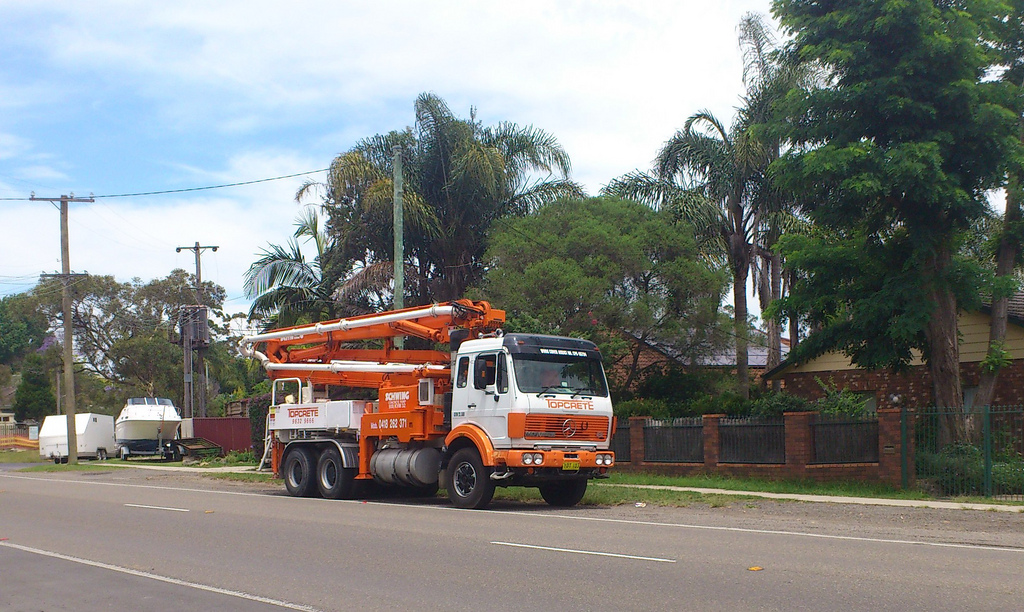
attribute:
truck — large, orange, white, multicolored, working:
[238, 290, 621, 521]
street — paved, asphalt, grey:
[2, 448, 1023, 612]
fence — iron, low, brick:
[586, 405, 929, 490]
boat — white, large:
[106, 394, 189, 455]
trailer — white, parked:
[36, 412, 121, 464]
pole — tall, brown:
[26, 190, 111, 468]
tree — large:
[735, 2, 1021, 503]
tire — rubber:
[434, 445, 495, 507]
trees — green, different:
[265, 8, 1023, 495]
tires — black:
[268, 438, 493, 506]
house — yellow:
[747, 260, 1023, 445]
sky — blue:
[1, 5, 794, 354]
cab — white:
[450, 329, 622, 478]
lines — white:
[6, 502, 1013, 611]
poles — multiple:
[33, 161, 246, 459]